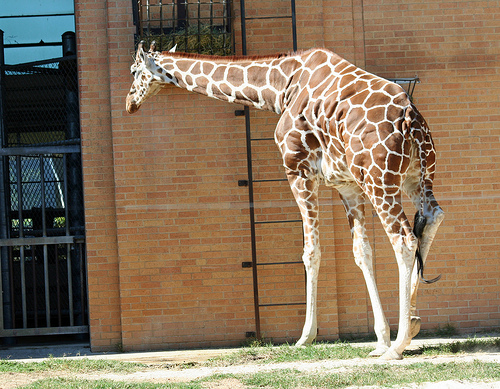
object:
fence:
[0, 72, 91, 327]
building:
[71, 0, 499, 347]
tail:
[404, 119, 432, 276]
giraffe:
[124, 39, 446, 359]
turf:
[0, 342, 498, 387]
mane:
[158, 47, 307, 64]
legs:
[291, 180, 424, 353]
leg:
[286, 170, 323, 343]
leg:
[339, 184, 392, 357]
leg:
[290, 175, 323, 349]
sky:
[0, 0, 75, 69]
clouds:
[0, 0, 74, 65]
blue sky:
[0, 0, 73, 75]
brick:
[113, 186, 132, 193]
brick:
[135, 183, 152, 190]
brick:
[172, 178, 190, 183]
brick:
[145, 191, 166, 198]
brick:
[115, 199, 136, 204]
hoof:
[411, 316, 422, 336]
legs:
[413, 152, 446, 349]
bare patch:
[29, 201, 499, 352]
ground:
[0, 330, 500, 387]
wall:
[77, 1, 499, 353]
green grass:
[203, 344, 346, 387]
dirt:
[152, 361, 211, 381]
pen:
[0, 0, 498, 386]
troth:
[135, 21, 230, 57]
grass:
[0, 328, 498, 388]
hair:
[163, 49, 288, 65]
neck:
[161, 51, 297, 115]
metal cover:
[127, 0, 236, 69]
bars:
[132, 0, 222, 41]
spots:
[308, 73, 352, 125]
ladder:
[233, 1, 307, 344]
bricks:
[383, 4, 490, 69]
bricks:
[83, 127, 233, 229]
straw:
[187, 29, 208, 49]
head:
[123, 36, 174, 114]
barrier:
[0, 144, 85, 345]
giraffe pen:
[0, 7, 495, 387]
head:
[126, 43, 172, 118]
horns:
[135, 39, 159, 57]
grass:
[273, 345, 354, 359]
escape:
[234, 1, 320, 344]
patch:
[255, 360, 350, 370]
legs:
[373, 178, 446, 361]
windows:
[131, 0, 236, 62]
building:
[76, 4, 484, 346]